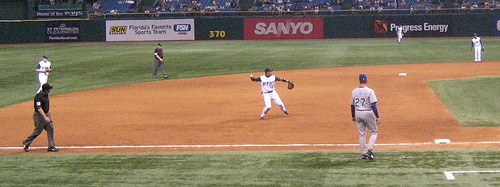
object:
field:
[0, 36, 500, 187]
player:
[244, 68, 294, 119]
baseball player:
[343, 73, 382, 158]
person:
[19, 82, 62, 152]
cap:
[41, 83, 53, 93]